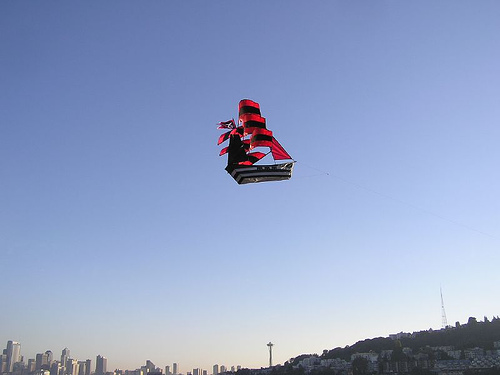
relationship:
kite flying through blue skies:
[212, 97, 297, 187] [0, 0, 497, 375]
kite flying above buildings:
[216, 99, 296, 185] [3, 338, 270, 370]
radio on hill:
[417, 274, 473, 334] [294, 316, 498, 373]